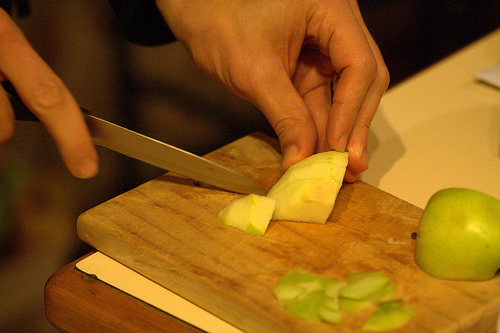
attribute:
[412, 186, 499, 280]
apple — sliced, green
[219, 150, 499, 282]
apple — sliced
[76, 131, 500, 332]
cutting board — brown, wooden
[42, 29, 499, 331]
table — wood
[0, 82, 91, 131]
knife handle — black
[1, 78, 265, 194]
knife — silver, stainless steel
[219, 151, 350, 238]
fruit — small, peeled, sliced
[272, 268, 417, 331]
peel — green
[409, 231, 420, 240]
stem — brown